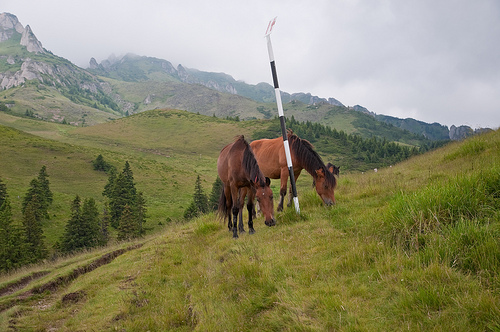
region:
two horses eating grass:
[210, 126, 345, 237]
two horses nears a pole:
[204, 128, 351, 242]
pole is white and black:
[259, 11, 310, 213]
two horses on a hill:
[80, 106, 496, 323]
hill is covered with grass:
[1, 137, 490, 330]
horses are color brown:
[197, 123, 352, 240]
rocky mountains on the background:
[4, 14, 313, 114]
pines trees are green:
[0, 133, 211, 268]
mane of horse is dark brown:
[237, 139, 264, 188]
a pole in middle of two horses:
[214, 3, 352, 232]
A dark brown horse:
[206, 129, 279, 238]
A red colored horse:
[258, 132, 340, 210]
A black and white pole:
[261, 24, 313, 224]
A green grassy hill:
[76, 241, 324, 324]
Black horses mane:
[238, 130, 273, 230]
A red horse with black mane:
[290, 128, 340, 208]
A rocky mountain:
[2, 12, 113, 118]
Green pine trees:
[2, 175, 149, 258]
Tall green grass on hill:
[381, 177, 494, 275]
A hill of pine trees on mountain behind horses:
[266, 110, 407, 167]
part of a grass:
[303, 213, 356, 267]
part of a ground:
[268, 241, 333, 303]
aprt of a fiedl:
[314, 255, 366, 327]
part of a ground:
[298, 221, 346, 283]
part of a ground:
[288, 293, 308, 307]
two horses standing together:
[215, 123, 337, 234]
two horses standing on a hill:
[209, 120, 342, 249]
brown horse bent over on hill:
[203, 133, 279, 238]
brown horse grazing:
[262, 133, 347, 220]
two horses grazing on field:
[224, 128, 349, 238]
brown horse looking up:
[211, 137, 275, 235]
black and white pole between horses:
[261, 30, 313, 220]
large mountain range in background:
[0, 7, 193, 134]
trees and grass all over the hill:
[1, 165, 152, 284]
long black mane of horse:
[238, 140, 259, 182]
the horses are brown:
[167, 130, 338, 227]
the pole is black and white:
[260, 37, 320, 207]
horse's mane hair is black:
[232, 142, 274, 193]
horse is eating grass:
[243, 171, 291, 231]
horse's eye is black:
[308, 174, 340, 201]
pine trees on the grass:
[9, 133, 191, 277]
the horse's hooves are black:
[211, 202, 295, 246]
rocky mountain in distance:
[5, 3, 133, 123]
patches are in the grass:
[1, 257, 111, 321]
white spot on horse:
[251, 180, 275, 200]